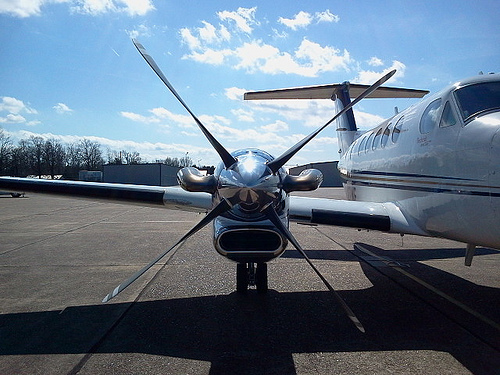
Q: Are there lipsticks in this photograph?
A: No, there are no lipsticks.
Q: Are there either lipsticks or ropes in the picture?
A: No, there are no lipsticks or ropes.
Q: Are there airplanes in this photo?
A: Yes, there is an airplane.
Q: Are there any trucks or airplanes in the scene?
A: Yes, there is an airplane.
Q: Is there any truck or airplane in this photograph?
A: Yes, there is an airplane.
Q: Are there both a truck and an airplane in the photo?
A: No, there is an airplane but no trucks.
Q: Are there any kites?
A: No, there are no kites.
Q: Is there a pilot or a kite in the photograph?
A: No, there are no kites or pilots.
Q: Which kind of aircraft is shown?
A: The aircraft is an airplane.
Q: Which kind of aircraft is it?
A: The aircraft is an airplane.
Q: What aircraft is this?
A: This is an airplane.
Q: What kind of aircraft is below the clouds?
A: The aircraft is an airplane.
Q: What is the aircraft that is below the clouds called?
A: The aircraft is an airplane.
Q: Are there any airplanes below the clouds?
A: Yes, there is an airplane below the clouds.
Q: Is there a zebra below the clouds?
A: No, there is an airplane below the clouds.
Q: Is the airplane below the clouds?
A: Yes, the airplane is below the clouds.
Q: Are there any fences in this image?
A: No, there are no fences.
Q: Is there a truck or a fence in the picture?
A: No, there are no fences or trucks.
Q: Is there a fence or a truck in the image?
A: No, there are no fences or trucks.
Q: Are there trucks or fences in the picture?
A: No, there are no fences or trucks.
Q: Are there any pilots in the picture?
A: No, there are no pilots.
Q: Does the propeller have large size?
A: Yes, the propeller is large.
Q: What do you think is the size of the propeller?
A: The propeller is large.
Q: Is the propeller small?
A: No, the propeller is large.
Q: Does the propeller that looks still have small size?
A: No, the propeller is large.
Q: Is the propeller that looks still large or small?
A: The propeller is large.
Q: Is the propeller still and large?
A: Yes, the propeller is still and large.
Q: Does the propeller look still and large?
A: Yes, the propeller is still and large.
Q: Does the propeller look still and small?
A: No, the propeller is still but large.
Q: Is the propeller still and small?
A: No, the propeller is still but large.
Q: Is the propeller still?
A: Yes, the propeller is still.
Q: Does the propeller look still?
A: Yes, the propeller is still.